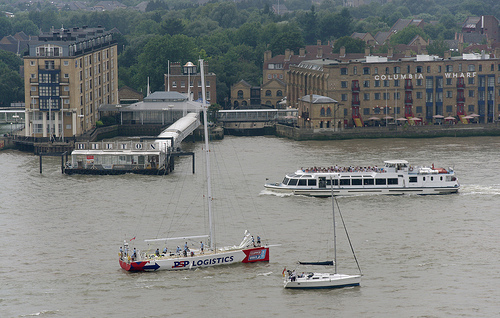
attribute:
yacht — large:
[260, 159, 460, 197]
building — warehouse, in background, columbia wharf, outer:
[291, 41, 500, 133]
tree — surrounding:
[334, 36, 367, 55]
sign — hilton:
[75, 142, 162, 154]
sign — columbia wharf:
[373, 71, 483, 81]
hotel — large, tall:
[22, 23, 122, 138]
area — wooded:
[139, 4, 279, 58]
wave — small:
[455, 209, 488, 227]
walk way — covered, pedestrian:
[218, 109, 287, 126]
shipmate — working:
[286, 268, 297, 277]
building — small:
[165, 57, 224, 103]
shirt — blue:
[176, 248, 182, 252]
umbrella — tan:
[410, 115, 423, 124]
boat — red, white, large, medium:
[118, 238, 270, 273]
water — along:
[15, 174, 111, 313]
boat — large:
[260, 159, 460, 197]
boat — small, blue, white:
[280, 271, 362, 291]